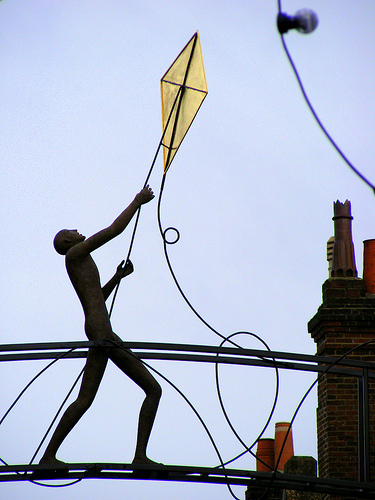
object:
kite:
[159, 30, 209, 177]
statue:
[37, 184, 166, 470]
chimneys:
[328, 199, 361, 277]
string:
[276, 0, 375, 192]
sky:
[0, 0, 374, 499]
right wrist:
[127, 200, 140, 211]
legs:
[97, 331, 162, 457]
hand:
[134, 182, 157, 205]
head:
[52, 228, 87, 256]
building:
[238, 200, 374, 499]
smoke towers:
[272, 421, 293, 473]